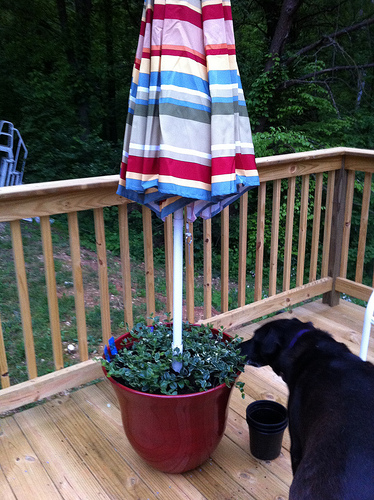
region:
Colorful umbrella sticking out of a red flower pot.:
[114, 0, 261, 223]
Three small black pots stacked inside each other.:
[244, 397, 286, 461]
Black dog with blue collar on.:
[233, 316, 371, 498]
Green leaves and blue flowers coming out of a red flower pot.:
[94, 310, 248, 398]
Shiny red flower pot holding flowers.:
[99, 318, 246, 474]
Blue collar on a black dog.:
[279, 326, 312, 352]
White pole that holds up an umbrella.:
[168, 208, 185, 352]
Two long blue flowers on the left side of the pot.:
[100, 336, 119, 363]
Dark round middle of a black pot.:
[251, 406, 283, 424]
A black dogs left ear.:
[262, 327, 281, 355]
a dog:
[240, 313, 373, 495]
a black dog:
[239, 305, 373, 498]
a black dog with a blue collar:
[240, 309, 372, 498]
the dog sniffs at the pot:
[120, 301, 370, 498]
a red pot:
[107, 316, 243, 471]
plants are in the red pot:
[102, 314, 252, 480]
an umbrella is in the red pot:
[100, 0, 268, 450]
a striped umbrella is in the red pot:
[108, 1, 260, 446]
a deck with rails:
[13, 153, 365, 497]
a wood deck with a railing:
[7, 153, 372, 497]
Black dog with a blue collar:
[236, 313, 369, 485]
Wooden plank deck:
[2, 411, 120, 495]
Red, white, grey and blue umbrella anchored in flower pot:
[119, 111, 255, 335]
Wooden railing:
[1, 178, 372, 302]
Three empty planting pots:
[244, 396, 288, 464]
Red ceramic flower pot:
[99, 370, 241, 474]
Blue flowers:
[99, 333, 128, 368]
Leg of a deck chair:
[358, 287, 372, 362]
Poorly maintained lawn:
[8, 227, 121, 335]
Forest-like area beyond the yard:
[7, 6, 126, 123]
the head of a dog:
[227, 309, 307, 372]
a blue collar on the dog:
[279, 324, 318, 361]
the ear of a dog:
[255, 327, 281, 363]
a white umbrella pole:
[164, 204, 202, 364]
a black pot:
[238, 389, 291, 467]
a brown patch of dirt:
[40, 236, 261, 334]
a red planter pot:
[95, 318, 248, 480]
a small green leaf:
[151, 347, 162, 361]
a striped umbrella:
[109, 1, 267, 226]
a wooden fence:
[0, 143, 373, 422]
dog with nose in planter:
[98, 307, 292, 411]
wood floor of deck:
[34, 404, 107, 484]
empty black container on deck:
[235, 394, 296, 464]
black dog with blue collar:
[244, 311, 357, 410]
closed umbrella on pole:
[119, 37, 255, 302]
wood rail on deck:
[280, 139, 341, 189]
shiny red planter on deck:
[118, 377, 238, 479]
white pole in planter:
[155, 275, 192, 374]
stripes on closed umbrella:
[133, 25, 247, 181]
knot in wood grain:
[23, 448, 41, 471]